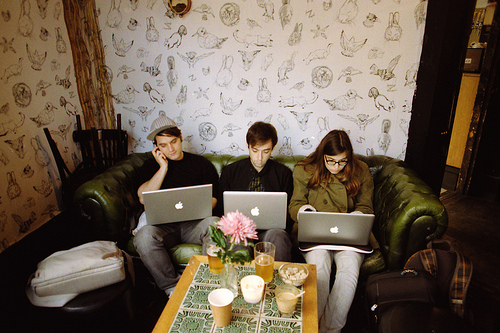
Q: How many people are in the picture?
A: Three.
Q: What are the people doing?
A: Using computers.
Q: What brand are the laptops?
A: Apple.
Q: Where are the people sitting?
A: On the couch.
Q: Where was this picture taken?
A: In a house.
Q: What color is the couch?
A: Green.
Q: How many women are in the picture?
A: One.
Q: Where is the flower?
A: On the table.